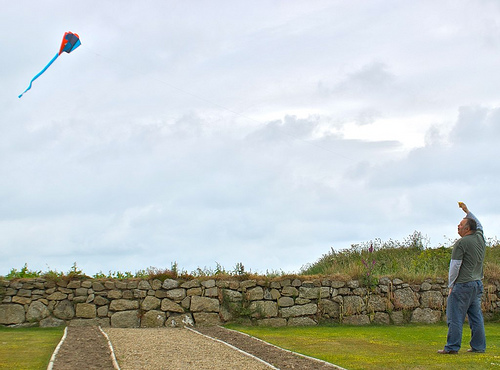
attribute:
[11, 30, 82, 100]
kite — flying, blue, red, colorful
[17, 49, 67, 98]
tail — blue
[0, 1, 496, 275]
air — light, cloudy, blue, white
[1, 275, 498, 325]
wall — short, stone, gray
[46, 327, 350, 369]
path — rock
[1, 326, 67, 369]
grass — bright green, green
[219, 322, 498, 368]
grass — trimmed, green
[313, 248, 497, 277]
grass — tall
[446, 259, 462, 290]
shirt — white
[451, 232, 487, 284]
shirt — green, short sleeved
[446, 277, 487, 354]
jeans — blue, large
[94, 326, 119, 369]
line — white, long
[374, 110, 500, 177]
cloud — white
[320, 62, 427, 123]
cloud — white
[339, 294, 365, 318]
stone — gray, large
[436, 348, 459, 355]
shoe — brown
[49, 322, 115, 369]
dirt — brown